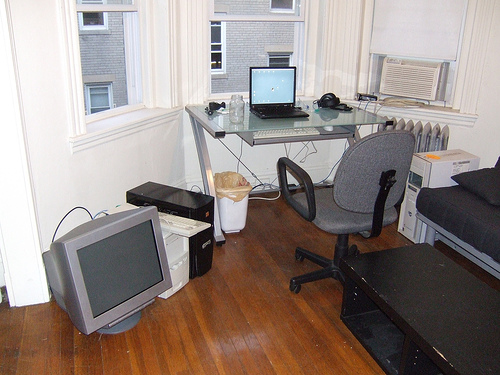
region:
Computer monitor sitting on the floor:
[40, 198, 185, 345]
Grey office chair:
[267, 112, 421, 304]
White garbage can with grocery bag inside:
[213, 165, 254, 227]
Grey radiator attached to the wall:
[375, 123, 462, 150]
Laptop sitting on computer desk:
[240, 58, 316, 122]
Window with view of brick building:
[67, 2, 179, 122]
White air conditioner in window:
[367, 50, 454, 105]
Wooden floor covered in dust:
[1, 187, 412, 374]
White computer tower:
[407, 146, 474, 253]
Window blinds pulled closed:
[367, 0, 457, 62]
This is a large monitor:
[41, 184, 161, 369]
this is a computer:
[90, 178, 160, 270]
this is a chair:
[296, 75, 406, 247]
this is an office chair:
[283, 104, 410, 313]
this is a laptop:
[236, 44, 363, 119]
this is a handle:
[268, 119, 310, 296]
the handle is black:
[213, 155, 343, 214]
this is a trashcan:
[203, 197, 251, 245]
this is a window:
[81, 33, 205, 120]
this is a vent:
[424, 129, 489, 154]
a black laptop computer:
[227, 57, 317, 127]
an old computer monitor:
[32, 197, 184, 340]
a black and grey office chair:
[268, 119, 436, 300]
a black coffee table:
[333, 243, 499, 373]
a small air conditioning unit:
[371, 48, 457, 102]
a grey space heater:
[363, 109, 472, 171]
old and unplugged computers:
[126, 168, 223, 314]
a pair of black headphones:
[310, 77, 346, 115]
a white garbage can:
[209, 160, 259, 241]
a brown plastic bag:
[203, 160, 255, 204]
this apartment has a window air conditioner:
[373, 50, 451, 105]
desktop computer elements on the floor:
[41, 178, 221, 336]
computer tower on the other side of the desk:
[396, 144, 482, 244]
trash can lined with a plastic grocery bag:
[209, 168, 254, 236]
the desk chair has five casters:
[273, 128, 417, 297]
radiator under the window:
[374, 113, 451, 156]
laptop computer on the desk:
[245, 61, 311, 121]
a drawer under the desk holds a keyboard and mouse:
[238, 121, 352, 143]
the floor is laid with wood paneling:
[3, 193, 349, 373]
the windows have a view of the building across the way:
[71, 0, 319, 127]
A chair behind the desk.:
[269, 131, 415, 263]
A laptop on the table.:
[238, 66, 315, 125]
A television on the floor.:
[28, 209, 170, 327]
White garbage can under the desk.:
[216, 168, 253, 232]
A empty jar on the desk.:
[226, 88, 249, 131]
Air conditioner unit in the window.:
[371, 52, 449, 104]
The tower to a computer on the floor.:
[396, 152, 460, 253]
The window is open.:
[219, 19, 302, 76]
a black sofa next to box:
[415, 166, 490, 248]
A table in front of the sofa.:
[351, 250, 487, 356]